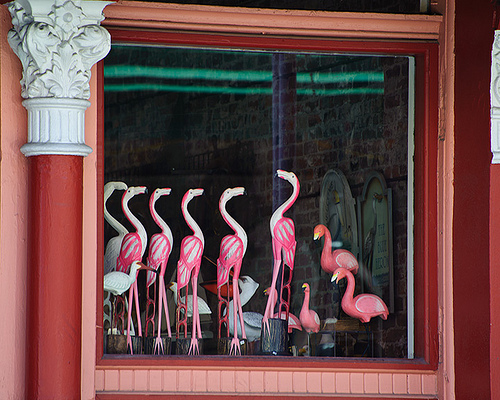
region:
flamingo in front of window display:
[102, 178, 123, 339]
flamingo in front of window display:
[122, 184, 146, 341]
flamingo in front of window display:
[146, 184, 174, 341]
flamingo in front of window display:
[173, 187, 205, 335]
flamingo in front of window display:
[213, 184, 245, 342]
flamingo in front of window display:
[262, 169, 294, 316]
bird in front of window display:
[100, 258, 158, 353]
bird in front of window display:
[312, 225, 359, 280]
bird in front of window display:
[293, 281, 324, 353]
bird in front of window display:
[330, 268, 388, 359]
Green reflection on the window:
[103, 63, 272, 96]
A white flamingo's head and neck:
[103, 180, 128, 236]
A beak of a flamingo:
[312, 230, 322, 242]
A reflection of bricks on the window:
[296, 98, 395, 171]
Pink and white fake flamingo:
[179, 186, 207, 356]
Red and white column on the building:
[3, 0, 117, 398]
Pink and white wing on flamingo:
[273, 216, 295, 251]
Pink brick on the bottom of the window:
[94, 368, 439, 395]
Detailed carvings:
[6, 0, 111, 156]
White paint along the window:
[406, 57, 414, 359]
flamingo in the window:
[300, 280, 328, 340]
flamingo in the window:
[330, 270, 400, 335]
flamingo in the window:
[311, 221, 347, 266]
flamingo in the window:
[265, 160, 303, 276]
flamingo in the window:
[218, 182, 243, 327]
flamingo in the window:
[183, 181, 208, 357]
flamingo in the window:
[150, 186, 175, 342]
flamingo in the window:
[121, 182, 147, 257]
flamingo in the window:
[110, 168, 126, 258]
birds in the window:
[109, 175, 403, 340]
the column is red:
[26, 152, 90, 398]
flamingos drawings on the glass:
[98, 170, 316, 361]